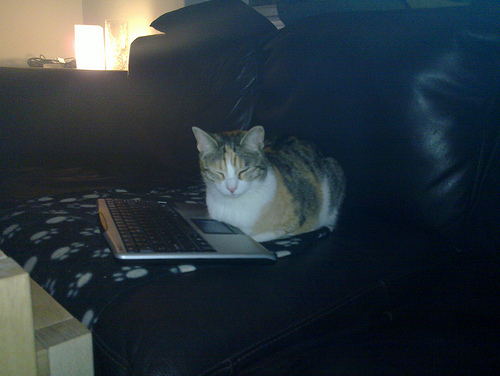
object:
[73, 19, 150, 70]
light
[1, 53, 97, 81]
table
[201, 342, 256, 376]
stitching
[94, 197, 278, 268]
laptop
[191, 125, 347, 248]
cat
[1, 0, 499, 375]
couch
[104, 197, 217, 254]
keyboard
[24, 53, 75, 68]
cords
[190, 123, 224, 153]
ears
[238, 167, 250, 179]
eyes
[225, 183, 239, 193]
nose